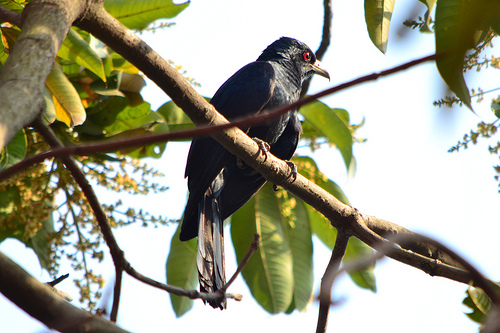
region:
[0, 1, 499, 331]
The bird is in a tree.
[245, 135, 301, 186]
The birds claws are wrapped around the branch on the tree.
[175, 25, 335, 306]
The bird is black.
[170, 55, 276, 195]
The bird has a wing.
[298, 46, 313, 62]
The bird has a red eye.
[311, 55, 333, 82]
The bird has a beak.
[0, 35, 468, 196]
A skinny branch on the tree.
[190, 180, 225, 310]
The bird has tail feathers.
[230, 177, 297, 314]
A green leaf on the tree.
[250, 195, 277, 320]
A vein on the center of the leaf.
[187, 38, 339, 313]
the bird on the branch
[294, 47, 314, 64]
the eye of the bird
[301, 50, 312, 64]
the eye is red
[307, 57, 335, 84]
the beak of the bird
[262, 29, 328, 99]
the head of the bird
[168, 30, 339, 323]
the bird is black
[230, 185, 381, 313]
the leaves on the branch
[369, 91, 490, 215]
the sky is blue and clear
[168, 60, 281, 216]
the wing of the bird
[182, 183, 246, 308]
the tail of the bird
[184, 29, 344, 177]
the bird on the branch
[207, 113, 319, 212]
the wing of the bird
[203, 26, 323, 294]
bird is black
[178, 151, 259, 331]
tail hanging over the branch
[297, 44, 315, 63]
red eye on the bird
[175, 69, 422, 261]
bird is sitting on a branch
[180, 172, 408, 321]
leaves below the bird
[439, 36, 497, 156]
yellow flowers on the tree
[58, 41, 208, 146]
leaves behind the bird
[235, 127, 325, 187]
talons of the bird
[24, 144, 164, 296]
yellow flowers under the leaves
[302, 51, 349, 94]
beak of the bird